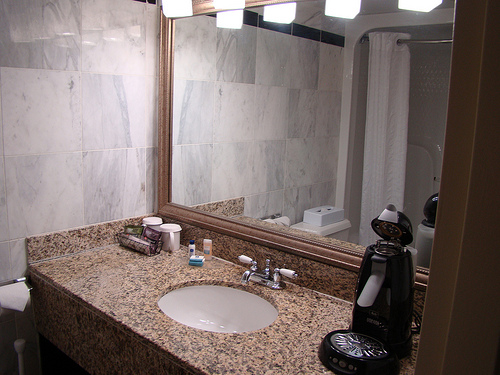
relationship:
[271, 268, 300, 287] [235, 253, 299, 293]
handle on faucet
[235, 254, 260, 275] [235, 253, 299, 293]
handle on faucet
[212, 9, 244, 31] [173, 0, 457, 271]
light above mirror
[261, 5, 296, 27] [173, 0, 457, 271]
light above mirror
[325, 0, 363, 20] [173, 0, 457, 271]
light above mirror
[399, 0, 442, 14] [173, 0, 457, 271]
light above mirror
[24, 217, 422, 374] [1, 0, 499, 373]
counter of bathroom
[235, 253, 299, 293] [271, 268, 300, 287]
faucet with handle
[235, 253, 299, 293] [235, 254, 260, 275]
faucet with handle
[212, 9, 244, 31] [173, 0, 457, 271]
light in mirror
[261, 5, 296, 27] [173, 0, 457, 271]
light in mirror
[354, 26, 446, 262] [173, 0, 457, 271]
shower in mirror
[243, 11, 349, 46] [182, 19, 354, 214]
strip on wall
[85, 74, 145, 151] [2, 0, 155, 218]
tile on wall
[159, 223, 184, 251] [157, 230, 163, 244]
cup at corner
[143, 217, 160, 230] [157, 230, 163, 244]
cup at corner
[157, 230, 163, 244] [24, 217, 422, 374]
corner of counter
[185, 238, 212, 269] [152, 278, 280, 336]
toiletries on sink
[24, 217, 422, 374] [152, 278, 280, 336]
counter of sink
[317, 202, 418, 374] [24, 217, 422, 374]
dispenser on counter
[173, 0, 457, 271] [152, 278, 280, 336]
mirror front sink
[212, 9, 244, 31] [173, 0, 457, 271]
light on mirror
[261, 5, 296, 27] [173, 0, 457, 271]
light on mirror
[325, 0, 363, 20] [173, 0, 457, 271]
light on mirror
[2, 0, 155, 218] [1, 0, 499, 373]
wall of bathroom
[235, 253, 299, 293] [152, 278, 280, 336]
faucet of sink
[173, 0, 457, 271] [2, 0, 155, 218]
mirror on wall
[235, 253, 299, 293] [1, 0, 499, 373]
faucet of bathroom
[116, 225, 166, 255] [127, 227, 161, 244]
basket of soaps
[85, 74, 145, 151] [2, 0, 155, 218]
tile for wall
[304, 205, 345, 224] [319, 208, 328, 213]
box of kleenex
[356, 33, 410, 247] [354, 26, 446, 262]
curtains for shower